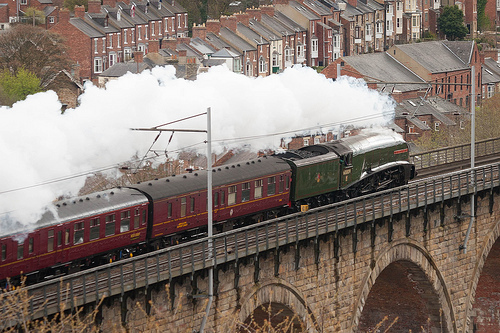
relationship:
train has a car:
[1, 130, 410, 257] [286, 131, 344, 217]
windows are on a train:
[74, 219, 106, 247] [1, 130, 410, 257]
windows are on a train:
[113, 207, 141, 233] [1, 130, 410, 257]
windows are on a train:
[176, 197, 200, 222] [1, 130, 410, 257]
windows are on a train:
[227, 179, 289, 202] [1, 130, 410, 257]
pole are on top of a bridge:
[205, 105, 215, 277] [7, 190, 499, 332]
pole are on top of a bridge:
[467, 65, 484, 233] [7, 190, 499, 332]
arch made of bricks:
[347, 235, 452, 329] [335, 285, 354, 296]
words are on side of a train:
[174, 219, 195, 232] [1, 130, 410, 257]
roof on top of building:
[73, 15, 103, 41] [51, 11, 113, 80]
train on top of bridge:
[1, 130, 410, 257] [7, 190, 499, 332]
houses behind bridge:
[107, 12, 467, 80] [7, 190, 499, 332]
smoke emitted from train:
[1, 71, 392, 175] [1, 130, 410, 257]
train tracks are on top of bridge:
[172, 216, 321, 264] [7, 190, 499, 332]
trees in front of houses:
[0, 30, 63, 103] [107, 12, 467, 80]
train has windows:
[1, 130, 410, 257] [74, 219, 106, 247]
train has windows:
[1, 130, 410, 257] [113, 207, 141, 233]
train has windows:
[1, 130, 410, 257] [176, 197, 200, 222]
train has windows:
[1, 130, 410, 257] [227, 179, 289, 202]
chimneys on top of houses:
[145, 9, 282, 35] [107, 12, 467, 80]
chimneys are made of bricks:
[145, 9, 282, 35] [213, 24, 217, 30]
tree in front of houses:
[436, 5, 472, 46] [107, 12, 467, 80]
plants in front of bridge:
[0, 300, 498, 332] [7, 190, 499, 332]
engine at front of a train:
[337, 138, 414, 203] [1, 130, 410, 257]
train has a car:
[1, 130, 410, 257] [150, 156, 289, 239]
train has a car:
[1, 130, 410, 257] [5, 192, 149, 286]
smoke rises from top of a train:
[1, 71, 392, 175] [1, 130, 410, 257]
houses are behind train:
[107, 12, 467, 80] [1, 130, 410, 257]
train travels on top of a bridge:
[1, 130, 410, 257] [7, 190, 499, 332]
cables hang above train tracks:
[179, 100, 470, 130] [172, 216, 321, 264]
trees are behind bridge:
[0, 30, 63, 103] [7, 190, 499, 332]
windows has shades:
[176, 197, 200, 222] [181, 199, 185, 218]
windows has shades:
[227, 179, 289, 202] [181, 199, 185, 218]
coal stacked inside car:
[295, 149, 321, 161] [286, 131, 344, 217]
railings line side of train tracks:
[234, 216, 316, 257] [172, 216, 321, 264]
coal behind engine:
[295, 149, 321, 161] [337, 138, 414, 203]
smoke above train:
[1, 71, 392, 175] [1, 130, 410, 257]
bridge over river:
[7, 190, 499, 332] [366, 323, 468, 333]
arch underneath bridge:
[347, 235, 452, 329] [7, 190, 499, 332]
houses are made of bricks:
[107, 12, 467, 80] [213, 24, 217, 30]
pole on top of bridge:
[205, 105, 215, 277] [7, 190, 499, 332]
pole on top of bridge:
[467, 65, 484, 233] [7, 190, 499, 332]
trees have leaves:
[0, 30, 63, 103] [25, 80, 35, 89]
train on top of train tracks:
[1, 130, 410, 257] [172, 216, 321, 264]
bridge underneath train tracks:
[7, 190, 499, 332] [172, 216, 321, 264]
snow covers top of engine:
[352, 140, 390, 152] [337, 138, 414, 203]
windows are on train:
[74, 219, 106, 247] [1, 130, 410, 257]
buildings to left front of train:
[324, 34, 499, 123] [1, 130, 410, 257]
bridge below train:
[7, 190, 499, 332] [1, 130, 410, 257]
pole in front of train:
[205, 105, 215, 277] [1, 130, 410, 257]